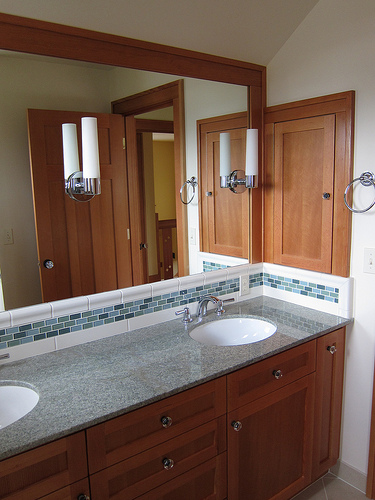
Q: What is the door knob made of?
A: Glass.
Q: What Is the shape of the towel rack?
A: Circle.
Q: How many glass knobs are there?
A: Seven.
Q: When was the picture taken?
A: Daytime.